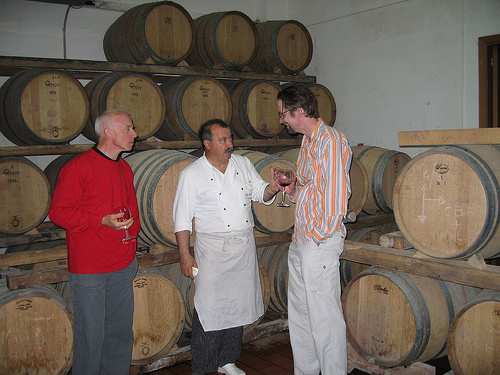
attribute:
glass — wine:
[270, 149, 315, 218]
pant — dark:
[66, 253, 138, 374]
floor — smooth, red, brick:
[252, 350, 285, 372]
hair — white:
[78, 102, 138, 144]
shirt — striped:
[292, 122, 345, 237]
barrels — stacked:
[95, 28, 316, 77]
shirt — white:
[172, 150, 275, 231]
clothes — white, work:
[169, 154, 269, 319]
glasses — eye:
[276, 96, 310, 121]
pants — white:
[287, 231, 344, 373]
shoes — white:
[184, 349, 269, 373]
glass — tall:
[107, 195, 148, 257]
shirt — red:
[52, 150, 144, 290]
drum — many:
[93, 2, 198, 74]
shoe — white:
[218, 357, 248, 373]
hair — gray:
[76, 90, 116, 144]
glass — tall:
[274, 167, 300, 209]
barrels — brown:
[102, 2, 312, 73]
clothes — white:
[172, 152, 271, 331]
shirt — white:
[170, 151, 277, 242]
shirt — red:
[49, 149, 139, 270]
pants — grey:
[67, 253, 135, 373]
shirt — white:
[174, 151, 272, 236]